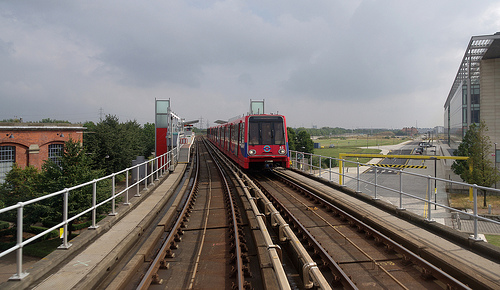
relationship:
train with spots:
[205, 114, 292, 173] [254, 133, 286, 171]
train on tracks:
[198, 110, 300, 178] [192, 139, 374, 288]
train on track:
[198, 110, 300, 178] [183, 131, 350, 286]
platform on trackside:
[142, 93, 179, 153] [181, 132, 212, 232]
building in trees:
[0, 118, 95, 209] [75, 117, 160, 185]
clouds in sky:
[90, 15, 409, 107] [0, 2, 443, 130]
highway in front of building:
[373, 134, 453, 214] [443, 40, 483, 184]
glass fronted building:
[435, 82, 475, 157] [436, 40, 481, 203]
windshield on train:
[249, 119, 285, 145] [201, 101, 299, 181]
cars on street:
[411, 140, 432, 152] [381, 136, 438, 200]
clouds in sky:
[0, 4, 437, 109] [0, 2, 443, 130]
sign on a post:
[59, 228, 64, 238] [63, 188, 68, 246]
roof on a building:
[0, 123, 89, 132] [0, 121, 84, 184]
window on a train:
[247, 117, 284, 144] [206, 110, 290, 171]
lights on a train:
[248, 149, 284, 154] [206, 110, 290, 171]